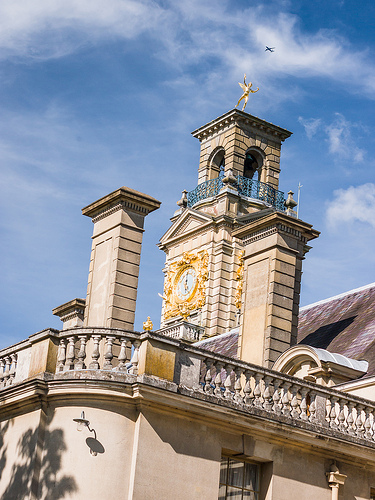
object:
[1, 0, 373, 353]
sky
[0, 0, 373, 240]
clouds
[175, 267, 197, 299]
clock face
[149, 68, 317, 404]
building tower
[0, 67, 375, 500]
building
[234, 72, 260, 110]
statue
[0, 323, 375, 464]
balcony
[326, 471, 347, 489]
watersprout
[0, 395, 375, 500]
wall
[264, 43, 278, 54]
airplane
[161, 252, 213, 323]
frame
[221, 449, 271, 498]
window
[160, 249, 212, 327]
clock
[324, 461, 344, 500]
pipes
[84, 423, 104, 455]
shadow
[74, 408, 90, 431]
lamp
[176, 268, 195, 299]
numbers